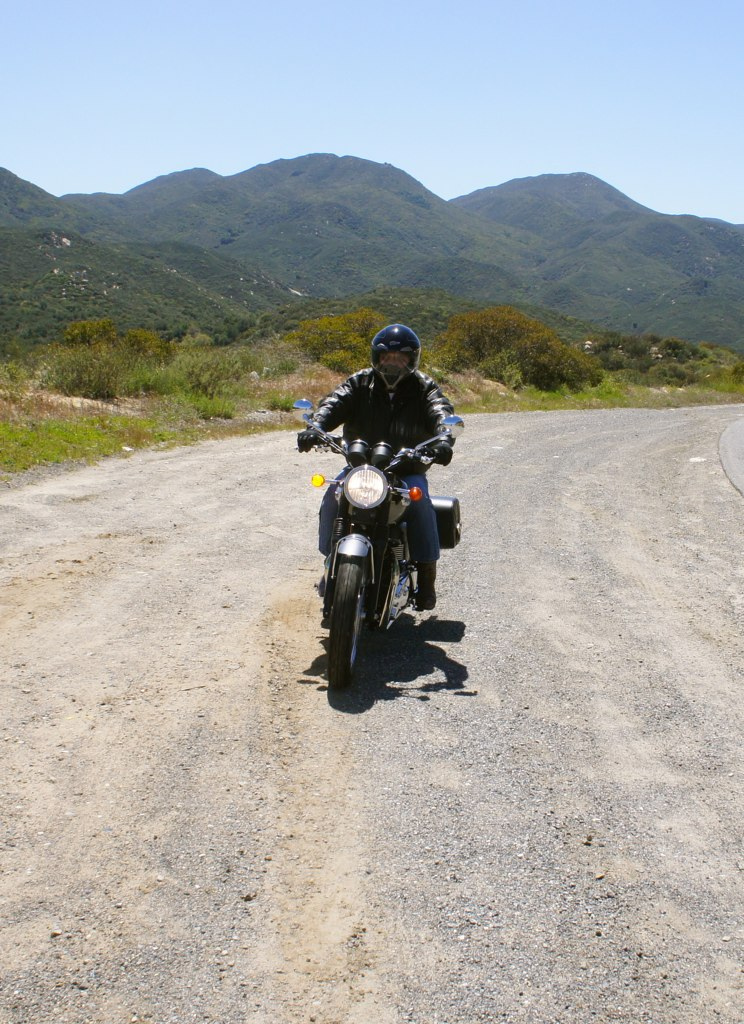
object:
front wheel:
[325, 551, 370, 693]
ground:
[0, 408, 744, 1020]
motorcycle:
[291, 396, 465, 690]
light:
[409, 485, 423, 502]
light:
[310, 471, 326, 488]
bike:
[292, 321, 467, 693]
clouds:
[597, 120, 612, 138]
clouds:
[151, 46, 161, 60]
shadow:
[300, 603, 479, 712]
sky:
[0, 0, 744, 237]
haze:
[0, 135, 741, 226]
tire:
[326, 561, 365, 690]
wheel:
[349, 590, 365, 669]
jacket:
[305, 367, 455, 478]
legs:
[403, 472, 441, 611]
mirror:
[292, 396, 316, 421]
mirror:
[439, 411, 466, 441]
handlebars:
[385, 444, 439, 474]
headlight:
[341, 460, 389, 513]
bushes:
[691, 366, 701, 382]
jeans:
[397, 474, 440, 561]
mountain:
[280, 239, 340, 294]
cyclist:
[295, 318, 456, 613]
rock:
[60, 228, 73, 248]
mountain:
[0, 150, 744, 343]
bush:
[452, 295, 570, 359]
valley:
[251, 258, 363, 303]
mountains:
[373, 218, 390, 250]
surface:
[443, 411, 464, 430]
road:
[0, 407, 744, 1014]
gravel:
[399, 796, 584, 912]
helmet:
[370, 320, 422, 403]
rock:
[239, 890, 254, 901]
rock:
[340, 922, 373, 977]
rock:
[577, 829, 602, 846]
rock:
[62, 970, 83, 998]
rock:
[274, 722, 296, 746]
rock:
[654, 964, 678, 986]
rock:
[515, 734, 544, 754]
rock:
[274, 742, 301, 767]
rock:
[449, 966, 474, 999]